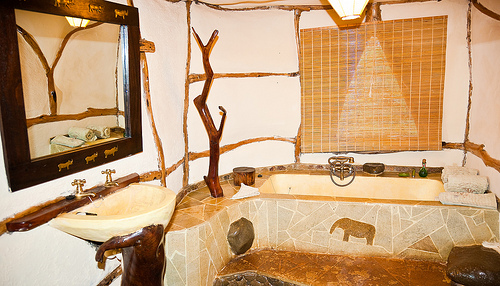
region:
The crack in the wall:
[226, 62, 286, 83]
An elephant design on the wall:
[325, 213, 377, 248]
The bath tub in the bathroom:
[262, 158, 451, 214]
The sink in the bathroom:
[51, 175, 178, 245]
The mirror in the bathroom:
[3, 3, 153, 178]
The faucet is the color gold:
[65, 166, 134, 200]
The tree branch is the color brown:
[190, 24, 235, 197]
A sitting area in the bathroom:
[216, 253, 321, 283]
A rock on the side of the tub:
[226, 212, 258, 259]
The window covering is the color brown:
[293, 13, 455, 155]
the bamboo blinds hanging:
[298, 15, 448, 152]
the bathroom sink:
[47, 182, 176, 243]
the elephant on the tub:
[330, 216, 375, 246]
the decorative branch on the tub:
[191, 27, 226, 199]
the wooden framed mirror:
[0, 0, 145, 195]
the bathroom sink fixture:
[70, 178, 95, 198]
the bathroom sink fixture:
[102, 167, 119, 189]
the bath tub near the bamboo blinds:
[256, 172, 443, 204]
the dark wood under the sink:
[95, 224, 167, 284]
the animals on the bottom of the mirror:
[57, 142, 118, 173]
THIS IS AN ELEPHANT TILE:
[316, 211, 377, 252]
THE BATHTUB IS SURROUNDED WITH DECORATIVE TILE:
[157, 187, 488, 283]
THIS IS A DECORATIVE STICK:
[185, 20, 247, 197]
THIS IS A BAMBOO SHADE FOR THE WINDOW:
[292, 11, 453, 157]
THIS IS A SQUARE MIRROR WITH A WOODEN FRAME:
[0, 0, 148, 178]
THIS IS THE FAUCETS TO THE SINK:
[65, 167, 118, 198]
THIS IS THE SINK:
[36, 175, 187, 255]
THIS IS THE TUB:
[262, 157, 457, 215]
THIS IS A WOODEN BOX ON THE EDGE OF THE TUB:
[222, 158, 257, 188]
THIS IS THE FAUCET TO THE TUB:
[324, 151, 361, 194]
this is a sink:
[253, 164, 443, 204]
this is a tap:
[331, 146, 363, 191]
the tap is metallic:
[331, 147, 353, 184]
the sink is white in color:
[131, 195, 166, 212]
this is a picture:
[29, 30, 119, 120]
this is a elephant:
[313, 201, 368, 248]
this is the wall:
[236, 12, 274, 92]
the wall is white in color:
[236, 18, 289, 65]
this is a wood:
[183, 32, 244, 191]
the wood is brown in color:
[191, 35, 226, 120]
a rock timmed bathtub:
[257, 160, 450, 225]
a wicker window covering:
[296, 13, 450, 158]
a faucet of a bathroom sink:
[69, 174, 96, 201]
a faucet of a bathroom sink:
[100, 167, 120, 194]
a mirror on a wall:
[7, 5, 142, 184]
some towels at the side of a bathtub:
[438, 163, 495, 212]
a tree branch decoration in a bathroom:
[190, 22, 238, 204]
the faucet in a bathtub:
[321, 149, 363, 189]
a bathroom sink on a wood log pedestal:
[75, 182, 194, 284]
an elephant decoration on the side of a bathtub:
[328, 213, 377, 248]